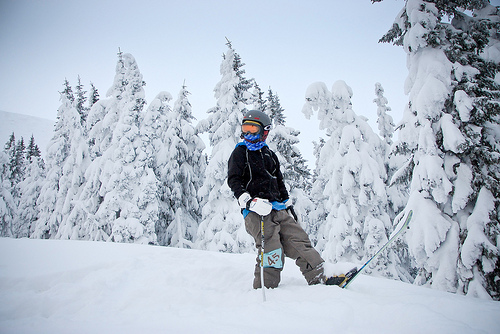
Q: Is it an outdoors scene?
A: Yes, it is outdoors.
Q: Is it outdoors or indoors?
A: It is outdoors.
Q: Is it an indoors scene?
A: No, it is outdoors.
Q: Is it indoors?
A: No, it is outdoors.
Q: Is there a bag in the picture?
A: No, there are no bags.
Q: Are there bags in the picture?
A: No, there are no bags.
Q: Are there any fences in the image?
A: No, there are no fences.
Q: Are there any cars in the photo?
A: No, there are no cars.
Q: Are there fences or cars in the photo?
A: No, there are no cars or fences.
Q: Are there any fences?
A: No, there are no fences.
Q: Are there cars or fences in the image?
A: No, there are no fences or cars.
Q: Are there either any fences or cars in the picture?
A: No, there are no fences or cars.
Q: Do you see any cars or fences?
A: No, there are no fences or cars.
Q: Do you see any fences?
A: No, there are no fences.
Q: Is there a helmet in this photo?
A: Yes, there is a helmet.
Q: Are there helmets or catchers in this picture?
A: Yes, there is a helmet.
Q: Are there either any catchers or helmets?
A: Yes, there is a helmet.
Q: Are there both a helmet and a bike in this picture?
A: No, there is a helmet but no bikes.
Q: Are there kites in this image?
A: No, there are no kites.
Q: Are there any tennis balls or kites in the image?
A: No, there are no kites or tennis balls.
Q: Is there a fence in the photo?
A: No, there are no fences.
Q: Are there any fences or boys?
A: No, there are no fences or boys.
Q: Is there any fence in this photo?
A: No, there are no fences.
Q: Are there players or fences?
A: No, there are no fences or players.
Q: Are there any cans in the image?
A: No, there are no cans.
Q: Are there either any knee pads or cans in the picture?
A: No, there are no cans or knee pads.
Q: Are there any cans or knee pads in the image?
A: No, there are no cans or knee pads.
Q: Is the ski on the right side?
A: Yes, the ski is on the right of the image.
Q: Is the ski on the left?
A: No, the ski is on the right of the image.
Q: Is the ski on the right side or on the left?
A: The ski is on the right of the image.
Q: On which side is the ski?
A: The ski is on the right of the image.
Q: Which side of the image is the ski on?
A: The ski is on the right of the image.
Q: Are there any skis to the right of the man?
A: Yes, there is a ski to the right of the man.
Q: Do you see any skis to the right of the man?
A: Yes, there is a ski to the right of the man.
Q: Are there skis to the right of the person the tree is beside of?
A: Yes, there is a ski to the right of the man.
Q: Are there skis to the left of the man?
A: No, the ski is to the right of the man.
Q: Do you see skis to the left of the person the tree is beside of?
A: No, the ski is to the right of the man.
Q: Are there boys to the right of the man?
A: No, there is a ski to the right of the man.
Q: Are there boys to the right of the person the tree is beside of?
A: No, there is a ski to the right of the man.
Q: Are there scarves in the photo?
A: Yes, there is a scarf.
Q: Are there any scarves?
A: Yes, there is a scarf.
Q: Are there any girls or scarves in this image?
A: Yes, there is a scarf.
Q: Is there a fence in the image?
A: No, there are no fences.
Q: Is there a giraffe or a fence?
A: No, there are no fences or giraffes.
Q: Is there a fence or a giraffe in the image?
A: No, there are no fences or giraffes.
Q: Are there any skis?
A: Yes, there are skis.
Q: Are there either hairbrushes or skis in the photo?
A: Yes, there are skis.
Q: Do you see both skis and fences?
A: No, there are skis but no fences.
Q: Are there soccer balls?
A: No, there are no soccer balls.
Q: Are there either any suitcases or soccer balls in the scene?
A: No, there are no soccer balls or suitcases.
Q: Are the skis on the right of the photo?
A: Yes, the skis are on the right of the image.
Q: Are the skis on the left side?
A: No, the skis are on the right of the image.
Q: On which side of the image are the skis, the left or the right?
A: The skis are on the right of the image.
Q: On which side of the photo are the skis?
A: The skis are on the right of the image.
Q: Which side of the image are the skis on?
A: The skis are on the right of the image.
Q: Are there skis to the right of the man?
A: Yes, there are skis to the right of the man.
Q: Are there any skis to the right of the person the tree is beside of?
A: Yes, there are skis to the right of the man.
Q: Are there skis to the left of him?
A: No, the skis are to the right of the man.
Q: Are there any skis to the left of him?
A: No, the skis are to the right of the man.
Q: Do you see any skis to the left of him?
A: No, the skis are to the right of the man.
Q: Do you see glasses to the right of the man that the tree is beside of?
A: No, there are skis to the right of the man.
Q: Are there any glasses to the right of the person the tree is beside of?
A: No, there are skis to the right of the man.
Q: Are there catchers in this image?
A: No, there are no catchers.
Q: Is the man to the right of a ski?
A: No, the man is to the left of a ski.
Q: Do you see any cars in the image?
A: No, there are no cars.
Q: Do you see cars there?
A: No, there are no cars.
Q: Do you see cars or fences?
A: No, there are no cars or fences.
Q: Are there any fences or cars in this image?
A: No, there are no cars or fences.